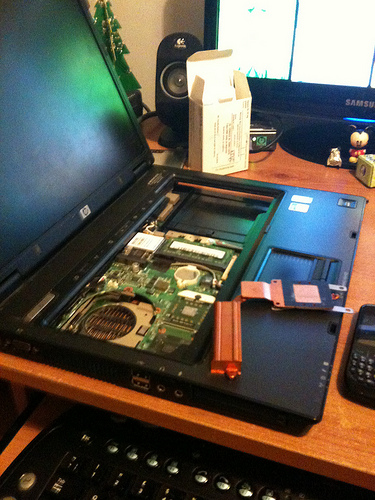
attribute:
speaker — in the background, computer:
[155, 30, 201, 150]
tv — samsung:
[210, 0, 343, 110]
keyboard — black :
[0, 401, 373, 499]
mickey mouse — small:
[346, 124, 373, 163]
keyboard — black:
[9, 418, 374, 499]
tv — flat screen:
[203, 1, 374, 163]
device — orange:
[212, 273, 349, 381]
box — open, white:
[169, 56, 288, 202]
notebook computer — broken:
[12, 127, 333, 398]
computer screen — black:
[36, 12, 68, 137]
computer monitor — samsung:
[201, 2, 373, 133]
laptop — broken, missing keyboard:
[1, 2, 366, 432]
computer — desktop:
[201, 0, 373, 169]